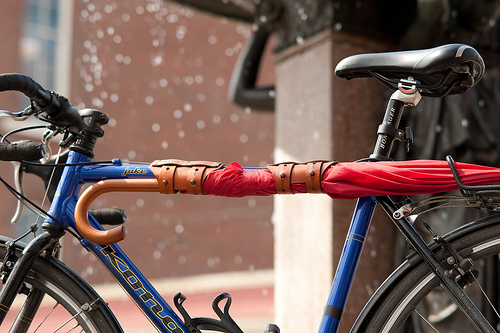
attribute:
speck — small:
[141, 88, 160, 112]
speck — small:
[169, 102, 185, 123]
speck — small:
[124, 143, 142, 167]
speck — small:
[226, 110, 245, 131]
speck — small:
[147, 49, 172, 75]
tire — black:
[328, 188, 499, 331]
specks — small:
[80, 4, 162, 63]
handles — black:
[3, 73, 108, 158]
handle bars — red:
[0, 62, 122, 226]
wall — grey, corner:
[265, 37, 426, 331]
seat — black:
[330, 41, 486, 98]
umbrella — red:
[73, 159, 497, 244]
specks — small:
[152, 54, 198, 86]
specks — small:
[139, 199, 189, 233]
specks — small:
[83, 37, 115, 87]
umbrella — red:
[50, 134, 498, 248]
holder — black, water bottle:
[171, 289, 279, 331]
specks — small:
[82, 19, 164, 84]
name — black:
[108, 246, 183, 331]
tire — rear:
[337, 212, 498, 325]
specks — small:
[59, 10, 267, 262]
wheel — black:
[0, 231, 120, 331]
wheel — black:
[349, 210, 485, 330]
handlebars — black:
[0, 69, 93, 138]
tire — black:
[0, 233, 128, 331]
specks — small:
[80, 1, 231, 160]